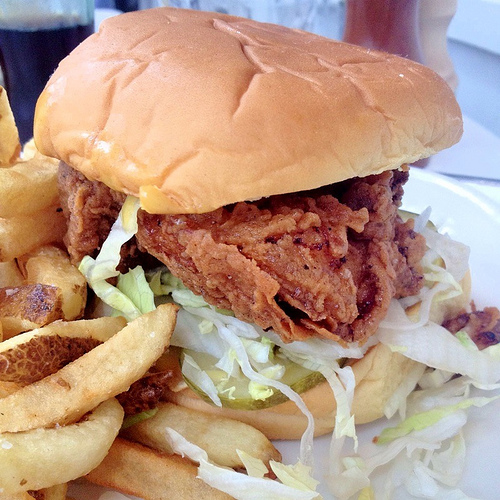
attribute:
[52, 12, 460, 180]
bun — mustard, top, brown, big, wrinkled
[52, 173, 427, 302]
chicken — fried, brown, cooked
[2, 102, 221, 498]
fries — crispy, golden, french, gold, yellow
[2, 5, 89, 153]
cup — full, black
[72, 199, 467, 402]
lettuce — green, fresh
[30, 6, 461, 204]
bread — 2 pieces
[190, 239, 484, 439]
bread — 2 pieces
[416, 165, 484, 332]
plate — small, white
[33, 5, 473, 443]
sandwich — chicken